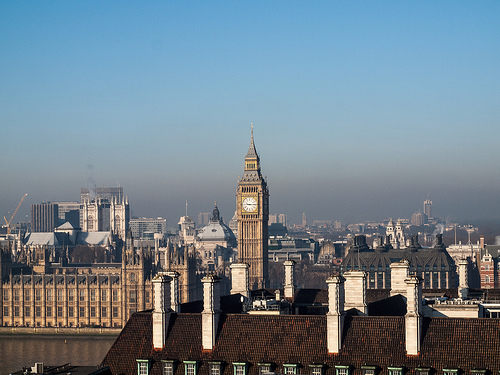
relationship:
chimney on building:
[342, 271, 369, 312] [94, 289, 494, 369]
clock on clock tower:
[240, 195, 260, 216] [238, 121, 270, 292]